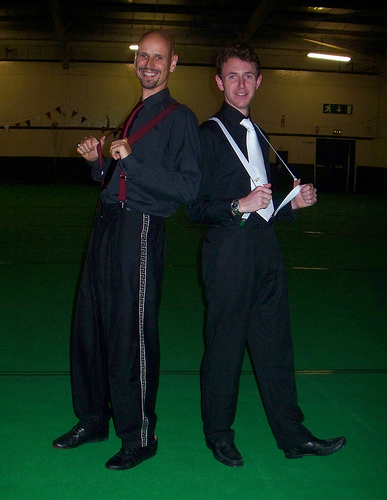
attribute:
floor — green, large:
[1, 183, 385, 499]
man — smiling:
[51, 26, 199, 472]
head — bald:
[131, 28, 180, 92]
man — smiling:
[185, 40, 344, 470]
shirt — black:
[85, 86, 203, 219]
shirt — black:
[182, 102, 298, 223]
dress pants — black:
[65, 201, 166, 447]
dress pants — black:
[193, 222, 314, 446]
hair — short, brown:
[213, 40, 260, 79]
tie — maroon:
[111, 101, 143, 154]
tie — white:
[238, 115, 275, 224]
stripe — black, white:
[133, 206, 154, 448]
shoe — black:
[278, 434, 348, 460]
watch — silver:
[228, 196, 242, 216]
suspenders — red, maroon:
[92, 101, 181, 210]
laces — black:
[118, 443, 137, 459]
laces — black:
[68, 421, 84, 437]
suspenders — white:
[205, 112, 303, 226]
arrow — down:
[335, 104, 342, 113]